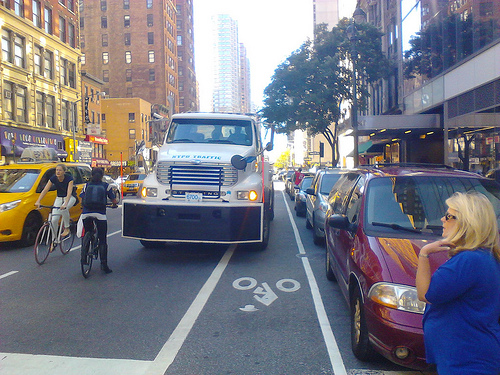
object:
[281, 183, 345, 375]
lines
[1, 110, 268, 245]
traffic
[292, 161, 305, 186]
person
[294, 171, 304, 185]
shirt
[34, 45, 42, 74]
window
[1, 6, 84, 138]
yellow building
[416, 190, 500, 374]
lady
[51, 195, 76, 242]
white pants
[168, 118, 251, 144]
windshield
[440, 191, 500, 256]
hair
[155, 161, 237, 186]
grill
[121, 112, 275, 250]
truck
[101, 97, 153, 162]
orange building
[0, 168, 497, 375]
street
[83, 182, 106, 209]
backpack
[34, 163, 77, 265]
woman riding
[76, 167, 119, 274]
person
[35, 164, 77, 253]
person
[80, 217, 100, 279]
bicycle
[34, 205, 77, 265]
bicycle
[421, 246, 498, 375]
shirt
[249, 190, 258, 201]
headlight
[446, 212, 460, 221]
glasses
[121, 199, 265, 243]
bumper